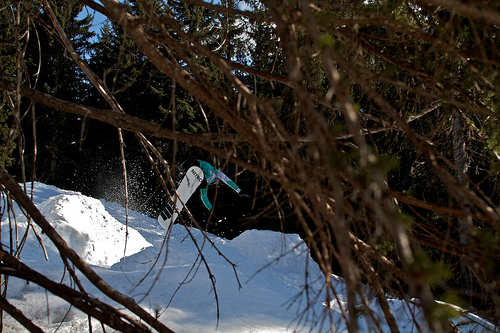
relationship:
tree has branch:
[1, 2, 497, 332] [1, 76, 498, 274]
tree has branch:
[1, 2, 497, 332] [100, 1, 266, 155]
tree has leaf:
[1, 2, 497, 332] [364, 153, 404, 175]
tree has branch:
[1, 2, 497, 332] [331, 49, 500, 222]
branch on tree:
[1, 76, 498, 274] [1, 2, 497, 332]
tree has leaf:
[1, 2, 497, 332] [388, 208, 416, 229]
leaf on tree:
[313, 31, 335, 51] [1, 2, 497, 332]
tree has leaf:
[1, 2, 497, 332] [313, 31, 335, 51]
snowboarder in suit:
[192, 159, 252, 216] [188, 157, 250, 212]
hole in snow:
[49, 306, 73, 322] [0, 178, 495, 331]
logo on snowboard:
[190, 167, 204, 183] [157, 164, 204, 228]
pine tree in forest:
[79, 16, 123, 105] [1, 1, 498, 324]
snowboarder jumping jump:
[192, 159, 252, 216] [14, 192, 156, 266]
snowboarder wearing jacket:
[192, 159, 252, 216] [199, 159, 241, 212]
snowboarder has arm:
[192, 159, 252, 216] [215, 166, 241, 193]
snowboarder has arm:
[192, 159, 252, 216] [201, 186, 213, 210]